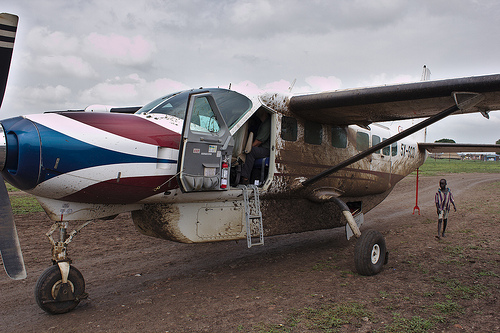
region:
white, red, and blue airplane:
[5, 18, 492, 285]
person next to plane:
[423, 172, 457, 234]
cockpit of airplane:
[153, 90, 264, 185]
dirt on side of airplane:
[106, 104, 415, 246]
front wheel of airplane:
[33, 257, 83, 315]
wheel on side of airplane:
[347, 233, 401, 269]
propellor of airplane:
[2, 8, 34, 287]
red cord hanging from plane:
[410, 170, 429, 217]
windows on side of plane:
[278, 120, 405, 158]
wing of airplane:
[284, 64, 495, 119]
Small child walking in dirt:
[428, 173, 465, 244]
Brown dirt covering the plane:
[284, 128, 396, 258]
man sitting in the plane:
[237, 103, 287, 195]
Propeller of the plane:
[0, 14, 40, 331]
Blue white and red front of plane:
[33, 95, 163, 219]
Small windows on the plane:
[280, 110, 410, 163]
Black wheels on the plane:
[24, 213, 104, 329]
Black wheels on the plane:
[311, 188, 395, 275]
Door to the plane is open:
[161, 77, 287, 216]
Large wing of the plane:
[279, 83, 496, 142]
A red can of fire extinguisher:
[219, 150, 229, 194]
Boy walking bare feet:
[433, 176, 458, 243]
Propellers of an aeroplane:
[0, 59, 32, 297]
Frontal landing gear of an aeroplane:
[27, 219, 91, 321]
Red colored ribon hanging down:
[407, 164, 427, 221]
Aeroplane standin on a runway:
[1, 60, 498, 329]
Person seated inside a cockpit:
[224, 102, 275, 194]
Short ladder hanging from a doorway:
[232, 172, 265, 256]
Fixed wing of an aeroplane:
[267, 68, 499, 120]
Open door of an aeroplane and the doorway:
[172, 89, 279, 197]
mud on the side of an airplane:
[263, 123, 410, 234]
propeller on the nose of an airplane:
[1, 8, 32, 284]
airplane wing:
[286, 70, 498, 172]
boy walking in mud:
[430, 171, 460, 243]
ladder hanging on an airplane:
[232, 181, 269, 255]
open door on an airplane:
[177, 88, 276, 194]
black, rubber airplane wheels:
[27, 225, 389, 313]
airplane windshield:
[125, 85, 251, 134]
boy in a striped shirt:
[434, 177, 455, 214]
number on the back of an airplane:
[399, 141, 417, 158]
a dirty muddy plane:
[1, 48, 469, 276]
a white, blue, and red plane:
[0, 48, 494, 305]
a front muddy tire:
[31, 238, 108, 315]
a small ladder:
[231, 180, 269, 252]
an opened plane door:
[180, 91, 276, 201]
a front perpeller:
[0, 8, 30, 293]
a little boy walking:
[428, 172, 464, 245]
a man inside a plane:
[231, 105, 281, 196]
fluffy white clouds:
[41, 33, 171, 97]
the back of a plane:
[351, 104, 448, 183]